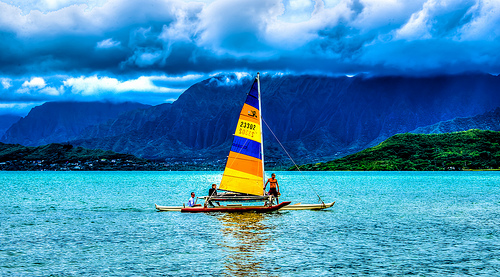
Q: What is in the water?
A: Sailboat.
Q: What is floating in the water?
A: Boat.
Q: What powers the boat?
A: Wind.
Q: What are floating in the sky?
A: Clouds.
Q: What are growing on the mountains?
A: Trees.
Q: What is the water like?
A: Calm.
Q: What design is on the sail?
A: Stripes.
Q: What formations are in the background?
A: Mountains.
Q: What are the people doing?
A: Sailing.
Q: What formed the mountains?
A: Plate tectonics.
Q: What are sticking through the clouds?
A: Mountains.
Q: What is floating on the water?
A: Sailboat.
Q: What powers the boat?
A: Wind.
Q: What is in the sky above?
A: Clouds.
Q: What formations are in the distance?
A: Mountains.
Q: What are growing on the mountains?
A: Trees.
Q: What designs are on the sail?
A: Stripes.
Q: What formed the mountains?
A: Plate tectonics.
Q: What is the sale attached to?
A: Mast.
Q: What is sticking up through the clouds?
A: Mountains.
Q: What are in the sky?
A: Clouds.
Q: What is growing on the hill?
A: Grass.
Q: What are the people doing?
A: Sailing.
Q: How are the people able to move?
A: Wind.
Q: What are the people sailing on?
A: Water.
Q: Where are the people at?
A: Ocean.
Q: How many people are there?
A: 3.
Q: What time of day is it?
A: Daytime.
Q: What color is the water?
A: Blue.